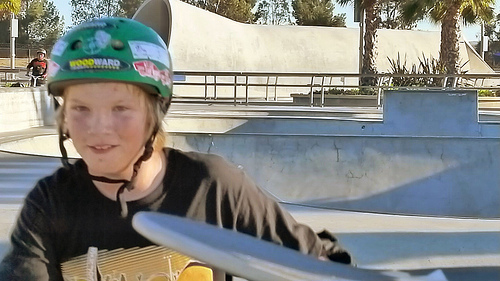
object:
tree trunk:
[338, 28, 401, 94]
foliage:
[335, 5, 486, 90]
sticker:
[64, 57, 129, 74]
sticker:
[79, 29, 111, 55]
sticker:
[124, 41, 174, 68]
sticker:
[130, 63, 174, 85]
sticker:
[43, 59, 60, 76]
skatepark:
[130, 205, 346, 279]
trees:
[329, 3, 499, 113]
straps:
[44, 94, 170, 194]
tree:
[329, 0, 408, 92]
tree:
[390, 0, 499, 87]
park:
[2, 3, 499, 277]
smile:
[82, 136, 122, 158]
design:
[74, 162, 494, 277]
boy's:
[17, 22, 217, 196]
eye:
[111, 102, 132, 112]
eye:
[71, 105, 91, 112]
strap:
[85, 171, 142, 196]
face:
[51, 82, 153, 181]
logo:
[63, 56, 130, 71]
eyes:
[69, 97, 137, 117]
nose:
[86, 105, 118, 142]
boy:
[7, 12, 353, 277]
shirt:
[8, 145, 343, 280]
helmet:
[46, 17, 173, 106]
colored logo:
[67, 59, 125, 72]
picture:
[56, 239, 228, 279]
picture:
[63, 57, 128, 76]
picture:
[125, 61, 173, 83]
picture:
[51, 37, 68, 52]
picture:
[123, 37, 174, 67]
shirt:
[19, 57, 47, 80]